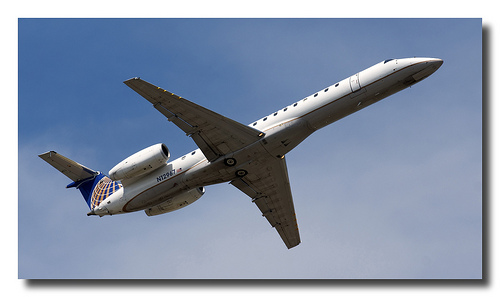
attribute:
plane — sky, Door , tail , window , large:
[44, 36, 437, 248]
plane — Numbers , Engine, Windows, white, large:
[33, 45, 448, 252]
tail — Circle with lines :
[44, 130, 124, 215]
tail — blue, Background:
[34, 142, 134, 223]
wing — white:
[130, 68, 313, 252]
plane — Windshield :
[39, 52, 443, 265]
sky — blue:
[48, 33, 142, 65]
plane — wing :
[119, 69, 309, 246]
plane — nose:
[370, 35, 450, 105]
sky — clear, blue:
[16, 16, 481, 280]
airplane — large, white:
[38, 56, 443, 248]